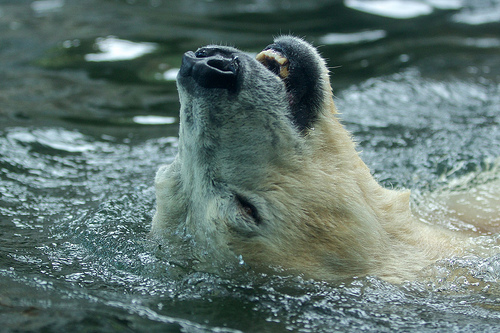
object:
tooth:
[274, 65, 289, 82]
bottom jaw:
[259, 33, 333, 139]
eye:
[230, 191, 257, 229]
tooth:
[261, 49, 283, 70]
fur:
[155, 146, 498, 300]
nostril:
[182, 49, 214, 64]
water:
[30, 212, 113, 250]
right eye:
[226, 187, 266, 227]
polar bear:
[152, 36, 499, 300]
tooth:
[255, 50, 265, 58]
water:
[0, 0, 496, 331]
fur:
[313, 180, 360, 252]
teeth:
[256, 39, 311, 81]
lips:
[260, 32, 322, 134]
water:
[35, 154, 181, 294]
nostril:
[180, 48, 233, 82]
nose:
[180, 48, 244, 98]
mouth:
[224, 32, 327, 128]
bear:
[148, 31, 498, 291]